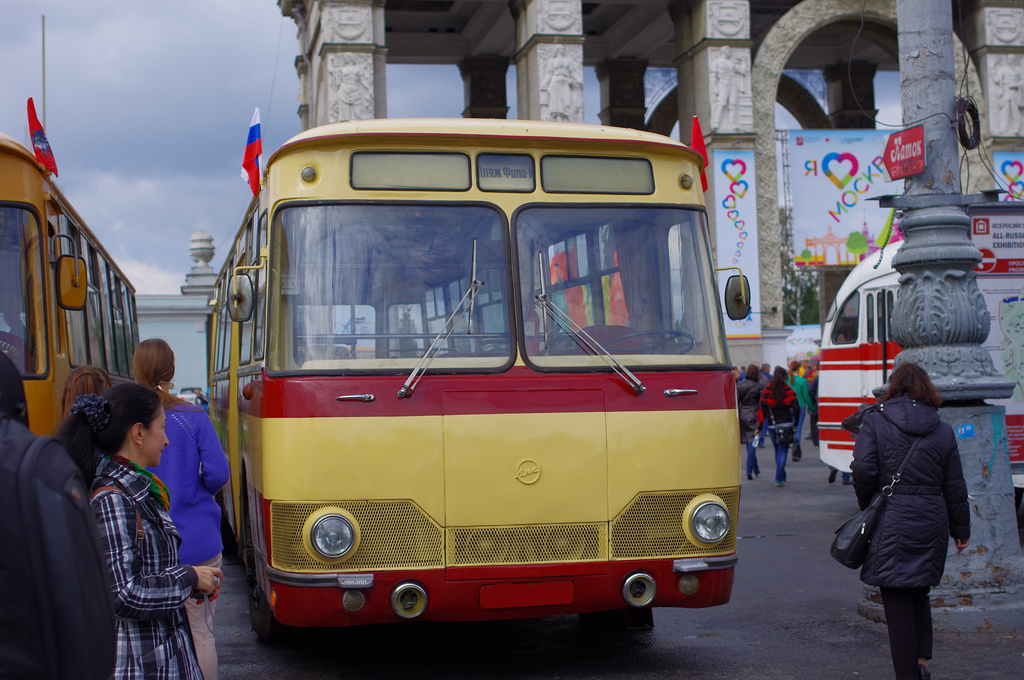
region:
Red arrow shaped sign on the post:
[881, 124, 933, 181]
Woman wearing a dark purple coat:
[832, 363, 969, 677]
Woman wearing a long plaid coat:
[60, 382, 220, 677]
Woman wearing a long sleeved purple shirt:
[133, 338, 236, 674]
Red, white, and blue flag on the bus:
[231, 105, 266, 197]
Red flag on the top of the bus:
[26, 88, 59, 177]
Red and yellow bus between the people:
[200, 117, 757, 626]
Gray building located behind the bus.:
[271, 0, 1021, 370]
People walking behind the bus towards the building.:
[739, 358, 823, 489]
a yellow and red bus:
[225, 128, 739, 618]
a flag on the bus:
[238, 105, 265, 181]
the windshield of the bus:
[277, 197, 717, 354]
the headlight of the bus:
[310, 506, 361, 563]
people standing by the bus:
[62, 339, 250, 660]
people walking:
[731, 345, 817, 486]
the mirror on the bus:
[217, 266, 249, 306]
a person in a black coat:
[830, 361, 971, 666]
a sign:
[779, 128, 885, 258]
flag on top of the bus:
[226, 99, 269, 195]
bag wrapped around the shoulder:
[816, 408, 941, 563]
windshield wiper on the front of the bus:
[388, 253, 487, 408]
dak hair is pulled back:
[56, 368, 170, 483]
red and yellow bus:
[192, 114, 752, 649]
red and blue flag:
[26, 96, 69, 176]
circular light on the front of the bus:
[684, 490, 733, 551]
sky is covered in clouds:
[4, 3, 951, 316]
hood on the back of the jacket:
[874, 392, 939, 435]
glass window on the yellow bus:
[256, 204, 523, 376]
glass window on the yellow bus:
[509, 197, 722, 378]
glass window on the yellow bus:
[1, 201, 46, 367]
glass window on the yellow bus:
[51, 204, 83, 360]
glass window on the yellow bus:
[81, 245, 102, 369]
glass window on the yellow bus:
[89, 248, 116, 372]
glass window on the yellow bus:
[220, 254, 233, 369]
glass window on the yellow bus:
[542, 155, 663, 198]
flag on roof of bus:
[240, 101, 270, 199]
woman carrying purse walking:
[821, 358, 980, 676]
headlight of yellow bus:
[302, 505, 366, 566]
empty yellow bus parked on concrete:
[199, 114, 750, 639]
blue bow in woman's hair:
[63, 383, 118, 422]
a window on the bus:
[539, 224, 691, 376]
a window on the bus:
[503, 133, 529, 201]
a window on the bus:
[558, 118, 658, 252]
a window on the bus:
[56, 219, 98, 355]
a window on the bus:
[93, 291, 122, 375]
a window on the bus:
[94, 272, 148, 386]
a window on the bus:
[293, 221, 443, 365]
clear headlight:
[688, 496, 737, 554]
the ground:
[768, 569, 822, 637]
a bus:
[255, 130, 726, 565]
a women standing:
[79, 386, 215, 675]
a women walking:
[834, 364, 989, 674]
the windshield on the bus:
[540, 215, 686, 356]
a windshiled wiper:
[419, 284, 484, 352]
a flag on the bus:
[240, 117, 267, 181]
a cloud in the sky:
[113, 48, 186, 115]